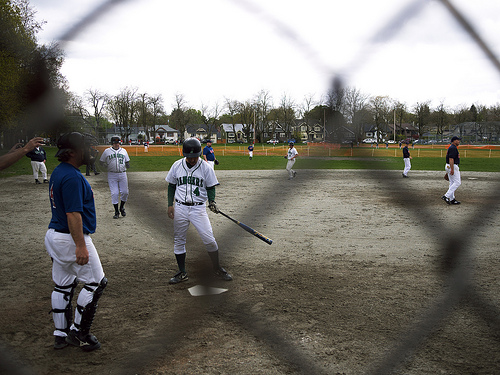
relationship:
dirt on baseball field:
[283, 228, 380, 277] [16, 113, 490, 366]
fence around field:
[347, 135, 390, 155] [253, 160, 408, 302]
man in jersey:
[158, 129, 244, 312] [164, 159, 216, 256]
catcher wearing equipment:
[43, 132, 109, 353] [50, 128, 99, 171]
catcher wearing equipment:
[43, 132, 109, 353] [46, 273, 109, 354]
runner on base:
[96, 134, 135, 219] [107, 205, 124, 217]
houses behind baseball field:
[100, 118, 478, 143] [4, 140, 499, 366]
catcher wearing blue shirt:
[39, 136, 111, 353] [47, 163, 100, 235]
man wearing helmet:
[166, 135, 238, 287] [180, 130, 204, 160]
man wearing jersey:
[166, 135, 238, 287] [164, 155, 221, 257]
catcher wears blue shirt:
[39, 136, 111, 353] [39, 167, 102, 238]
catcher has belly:
[43, 132, 109, 353] [76, 185, 101, 234]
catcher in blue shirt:
[43, 132, 109, 353] [47, 163, 100, 235]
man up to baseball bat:
[166, 135, 238, 287] [209, 204, 274, 245]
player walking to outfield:
[376, 121, 425, 201] [287, 133, 407, 203]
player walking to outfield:
[424, 121, 474, 224] [287, 133, 407, 203]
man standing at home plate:
[166, 135, 238, 287] [182, 279, 232, 306]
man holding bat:
[166, 135, 238, 287] [218, 209, 273, 244]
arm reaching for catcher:
[4, 122, 60, 182] [43, 132, 109, 353]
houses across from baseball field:
[255, 123, 313, 142] [0, 140, 500, 374]